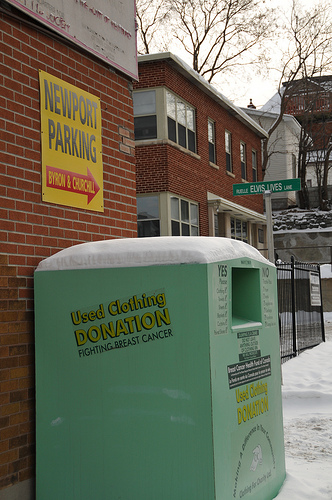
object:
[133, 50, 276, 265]
building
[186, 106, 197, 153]
window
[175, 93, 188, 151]
window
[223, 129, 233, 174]
window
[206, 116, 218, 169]
window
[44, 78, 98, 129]
writing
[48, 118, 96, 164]
writing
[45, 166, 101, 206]
arrow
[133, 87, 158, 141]
windows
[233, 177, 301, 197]
sign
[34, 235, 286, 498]
box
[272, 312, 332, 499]
street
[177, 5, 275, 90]
trees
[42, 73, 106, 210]
sign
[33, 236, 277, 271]
snow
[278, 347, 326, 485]
snow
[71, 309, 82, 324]
letters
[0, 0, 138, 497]
brick building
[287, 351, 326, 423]
snow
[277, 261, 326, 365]
fence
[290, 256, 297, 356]
metal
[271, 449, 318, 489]
ground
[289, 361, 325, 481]
ground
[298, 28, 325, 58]
leaves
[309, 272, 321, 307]
sign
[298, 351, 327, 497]
area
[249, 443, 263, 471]
clothing